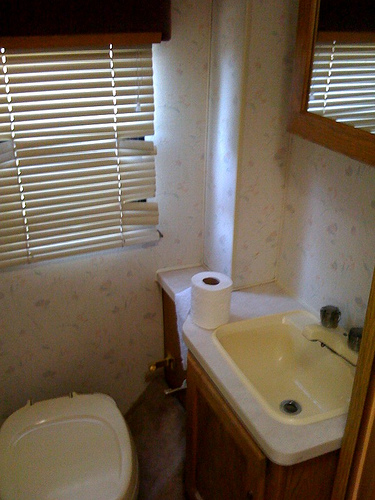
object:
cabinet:
[151, 259, 375, 500]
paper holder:
[150, 354, 188, 396]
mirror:
[286, 0, 375, 167]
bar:
[149, 354, 187, 397]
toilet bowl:
[0, 390, 141, 500]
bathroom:
[0, 0, 375, 500]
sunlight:
[0, 46, 167, 265]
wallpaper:
[0, 0, 375, 424]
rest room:
[0, 0, 375, 500]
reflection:
[306, 38, 375, 134]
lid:
[0, 389, 140, 500]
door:
[173, 349, 267, 500]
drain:
[278, 398, 302, 417]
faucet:
[302, 304, 364, 367]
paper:
[174, 271, 233, 372]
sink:
[180, 307, 364, 468]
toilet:
[0, 391, 142, 500]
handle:
[320, 304, 342, 329]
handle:
[347, 325, 364, 352]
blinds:
[0, 40, 163, 267]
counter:
[156, 264, 375, 466]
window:
[0, 0, 172, 281]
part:
[252, 288, 275, 302]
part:
[328, 28, 353, 62]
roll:
[190, 271, 233, 330]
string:
[134, 46, 143, 113]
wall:
[0, 1, 375, 420]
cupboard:
[150, 264, 375, 498]